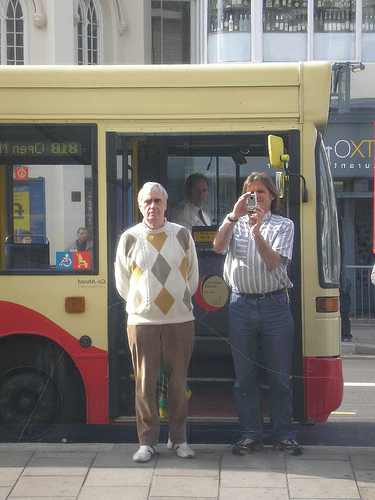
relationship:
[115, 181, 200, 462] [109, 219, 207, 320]
man has sweater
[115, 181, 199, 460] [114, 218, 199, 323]
man in sweater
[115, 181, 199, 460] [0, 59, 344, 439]
man near bus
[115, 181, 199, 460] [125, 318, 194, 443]
man has pants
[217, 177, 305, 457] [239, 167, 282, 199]
man has hair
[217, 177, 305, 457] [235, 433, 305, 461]
man has shoes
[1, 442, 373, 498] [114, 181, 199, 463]
sidewalk near men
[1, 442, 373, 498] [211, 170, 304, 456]
sidewalk near men